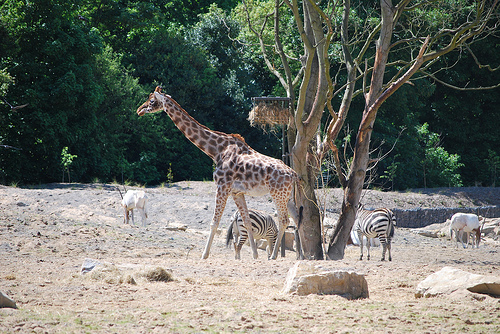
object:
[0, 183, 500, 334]
ground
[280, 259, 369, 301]
rock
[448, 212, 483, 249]
antelope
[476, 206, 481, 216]
horns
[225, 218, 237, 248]
tail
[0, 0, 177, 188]
green trees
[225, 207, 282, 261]
zebra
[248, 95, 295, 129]
giraffe hopper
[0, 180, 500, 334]
light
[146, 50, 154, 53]
leaves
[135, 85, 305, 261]
animals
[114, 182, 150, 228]
white antelope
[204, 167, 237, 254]
leg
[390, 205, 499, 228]
barrier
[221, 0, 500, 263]
tree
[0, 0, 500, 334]
zoo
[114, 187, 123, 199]
horns